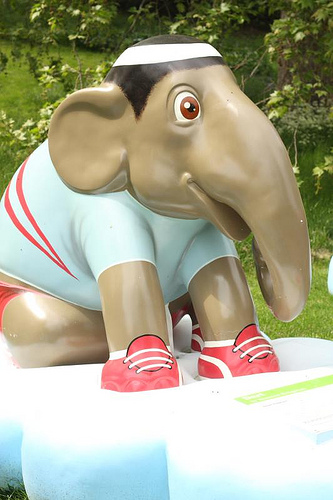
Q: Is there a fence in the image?
A: No, there are no fences.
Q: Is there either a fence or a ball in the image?
A: No, there are no fences or balls.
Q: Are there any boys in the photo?
A: No, there are no boys.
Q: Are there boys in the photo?
A: No, there are no boys.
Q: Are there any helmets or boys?
A: No, there are no boys or helmets.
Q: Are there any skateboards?
A: No, there are no skateboards.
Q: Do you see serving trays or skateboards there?
A: No, there are no skateboards or serving trays.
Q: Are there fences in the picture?
A: No, there are no fences.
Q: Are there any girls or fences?
A: No, there are no fences or girls.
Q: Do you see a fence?
A: No, there are no fences.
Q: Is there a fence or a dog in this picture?
A: No, there are no fences or dogs.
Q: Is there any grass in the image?
A: Yes, there is grass.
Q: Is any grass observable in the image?
A: Yes, there is grass.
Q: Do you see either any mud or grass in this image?
A: Yes, there is grass.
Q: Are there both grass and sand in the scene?
A: No, there is grass but no sand.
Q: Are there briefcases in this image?
A: No, there are no briefcases.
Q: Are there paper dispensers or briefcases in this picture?
A: No, there are no briefcases or paper dispensers.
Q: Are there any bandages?
A: No, there are no bandages.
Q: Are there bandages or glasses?
A: No, there are no bandages or glasses.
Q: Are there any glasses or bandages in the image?
A: No, there are no bandages or glasses.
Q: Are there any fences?
A: No, there are no fences.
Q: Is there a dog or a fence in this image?
A: No, there are no fences or dogs.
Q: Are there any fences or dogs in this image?
A: No, there are no fences or dogs.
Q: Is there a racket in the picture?
A: No, there are no rackets.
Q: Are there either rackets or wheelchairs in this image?
A: No, there are no rackets or wheelchairs.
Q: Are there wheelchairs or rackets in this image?
A: No, there are no rackets or wheelchairs.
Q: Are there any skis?
A: No, there are no skis.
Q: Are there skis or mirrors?
A: No, there are no skis or mirrors.